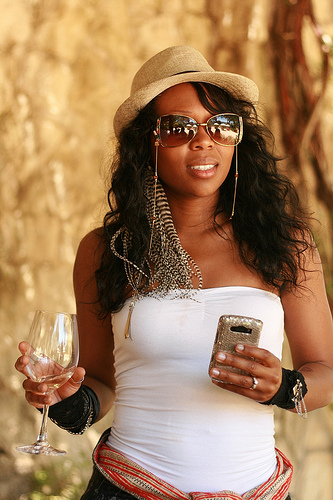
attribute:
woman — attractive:
[13, 42, 331, 500]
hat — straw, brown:
[110, 42, 260, 143]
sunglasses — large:
[150, 111, 244, 151]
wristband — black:
[262, 364, 309, 412]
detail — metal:
[291, 375, 310, 419]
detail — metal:
[59, 411, 93, 438]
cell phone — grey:
[207, 313, 262, 387]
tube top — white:
[104, 282, 287, 498]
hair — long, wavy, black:
[82, 81, 326, 327]